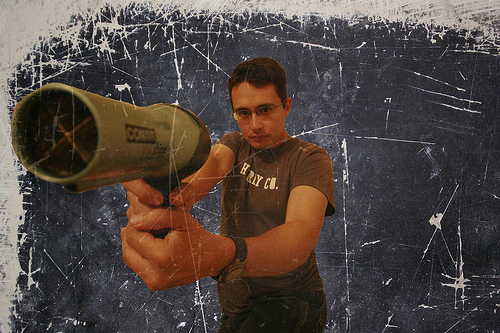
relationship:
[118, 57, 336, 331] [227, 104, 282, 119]
man wearing eyeglasses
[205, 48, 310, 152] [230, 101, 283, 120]
man wearing eyeglasses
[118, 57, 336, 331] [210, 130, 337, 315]
man wearing a shirt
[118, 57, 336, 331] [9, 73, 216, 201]
man holding blow dryer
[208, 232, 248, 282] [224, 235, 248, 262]
watch has band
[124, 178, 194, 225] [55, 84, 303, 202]
hand holding hair dryer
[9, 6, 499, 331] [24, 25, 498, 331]
black wall with white marks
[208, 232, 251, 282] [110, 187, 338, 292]
watch on a mans arm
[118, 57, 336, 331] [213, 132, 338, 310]
man wears shirt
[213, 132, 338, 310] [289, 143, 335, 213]
shirt has sleeve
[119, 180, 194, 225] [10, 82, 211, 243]
hand holds blow dryer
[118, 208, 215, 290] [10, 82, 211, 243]
hand holds blow dryer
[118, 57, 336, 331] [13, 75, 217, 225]
man holds blow dryer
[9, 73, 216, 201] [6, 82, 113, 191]
blow dryer has nozzle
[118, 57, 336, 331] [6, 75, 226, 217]
man holds blow dryer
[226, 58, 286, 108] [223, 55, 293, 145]
brown hair on head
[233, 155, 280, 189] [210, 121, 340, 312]
logo on shirt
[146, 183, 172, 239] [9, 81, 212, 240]
handle on blow dryer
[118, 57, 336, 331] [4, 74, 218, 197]
man holds something